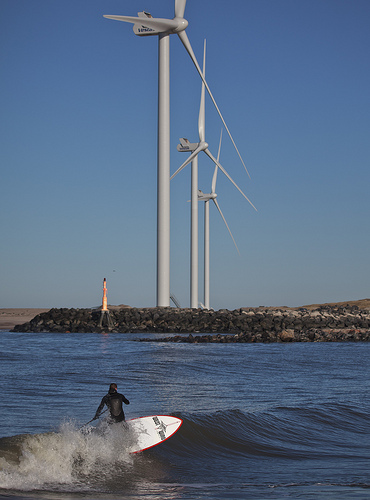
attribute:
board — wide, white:
[101, 411, 185, 458]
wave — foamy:
[1, 397, 370, 500]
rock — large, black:
[350, 307, 362, 317]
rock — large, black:
[303, 329, 317, 340]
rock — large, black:
[257, 320, 278, 330]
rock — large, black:
[127, 307, 143, 317]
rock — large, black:
[149, 311, 163, 323]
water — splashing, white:
[1, 325, 369, 498]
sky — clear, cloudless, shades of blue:
[1, 1, 369, 313]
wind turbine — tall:
[99, 1, 253, 325]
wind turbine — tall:
[167, 32, 263, 312]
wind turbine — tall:
[184, 124, 246, 315]